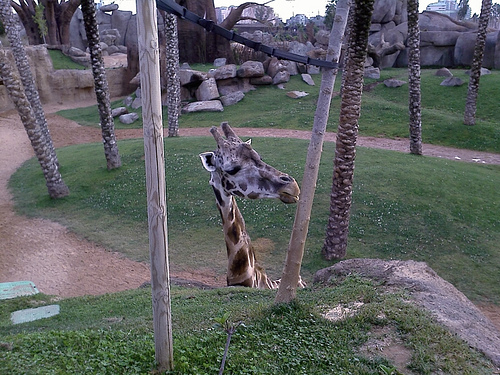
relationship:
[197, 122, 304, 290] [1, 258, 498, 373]
giraffe peaking over hill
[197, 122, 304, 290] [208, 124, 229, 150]
giraffe has horn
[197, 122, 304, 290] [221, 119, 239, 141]
giraffe has horn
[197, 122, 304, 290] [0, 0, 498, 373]
giraffe living in zoo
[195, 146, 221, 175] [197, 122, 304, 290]
right ear of a giraffe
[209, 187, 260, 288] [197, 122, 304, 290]
neck of a giraffe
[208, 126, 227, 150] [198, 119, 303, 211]
horn on giraffe's head